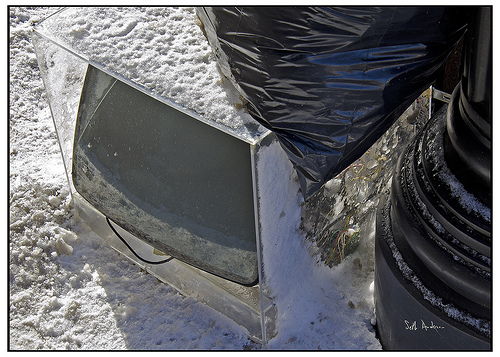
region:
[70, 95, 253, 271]
a tv screen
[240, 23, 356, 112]
a black plastic bag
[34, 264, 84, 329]
the snow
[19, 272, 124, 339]
the snow is white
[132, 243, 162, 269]
a black cord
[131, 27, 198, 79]
snow on the tv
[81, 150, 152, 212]
a reflection in the screen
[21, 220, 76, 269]
rocks in the snow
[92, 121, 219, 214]
a blank screen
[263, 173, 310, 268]
snow on the side of tv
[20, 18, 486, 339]
garbage left by pole in snow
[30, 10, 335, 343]
plastic case over television screen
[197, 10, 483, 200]
corner of filled garbage bag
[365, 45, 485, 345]
black pole of rings of different widths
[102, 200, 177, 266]
black wire curved in front of screen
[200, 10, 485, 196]
triangular edges of wrinkled bag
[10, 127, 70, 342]
gray ice on white snow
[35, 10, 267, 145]
textured snow in top of case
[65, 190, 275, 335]
narrow plastic panel under screen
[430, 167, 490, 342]
snow lining curved levels of pole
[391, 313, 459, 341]
name in bottom right corner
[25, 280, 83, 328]
light hitting the ground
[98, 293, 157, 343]
shadow on the ground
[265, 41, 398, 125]
bag in the photo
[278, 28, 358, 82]
light hitting the bag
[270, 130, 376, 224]
tip of the bag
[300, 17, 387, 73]
middle part of the bag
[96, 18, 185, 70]
white stuff in the photo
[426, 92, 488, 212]
black object in the photo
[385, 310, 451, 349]
name written in white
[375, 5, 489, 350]
Base of outdoor lamppost.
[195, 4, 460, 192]
Trash bag on top of TV in outdoor setting.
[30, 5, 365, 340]
Small television set on the snowy outdoor ground.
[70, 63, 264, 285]
Blank screen of a discarded television.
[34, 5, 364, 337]
Television with snow on top.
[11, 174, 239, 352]
Snow on the outdoor ground.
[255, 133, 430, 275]
The side of a transparent television set.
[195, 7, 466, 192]
Black plastic contractor trash bag.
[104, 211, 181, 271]
Loose wire coming out of a discarded television set's screen.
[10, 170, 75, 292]
Pile of dirty snow.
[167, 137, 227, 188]
part of a mirror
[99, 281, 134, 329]
part of a shade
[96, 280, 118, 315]
edge of a shade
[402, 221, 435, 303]
part of a tank